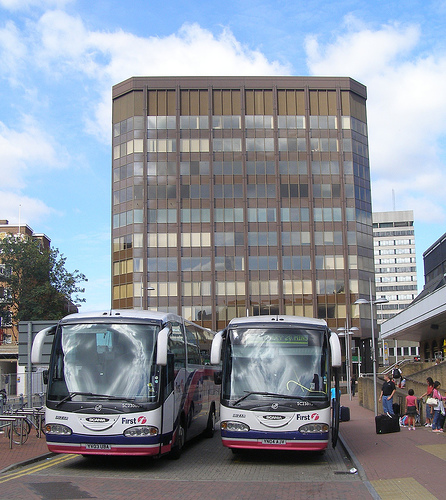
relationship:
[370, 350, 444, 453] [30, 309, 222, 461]
people in bus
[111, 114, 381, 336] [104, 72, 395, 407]
windows on building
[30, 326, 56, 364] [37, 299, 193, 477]
mirror on bus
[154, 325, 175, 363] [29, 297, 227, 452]
mirror on bus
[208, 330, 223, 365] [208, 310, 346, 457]
mirror on bus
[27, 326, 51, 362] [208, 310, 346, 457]
mirror on bus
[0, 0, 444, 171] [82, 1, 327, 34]
cloud on blue sky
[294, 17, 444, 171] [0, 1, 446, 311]
cloud on sky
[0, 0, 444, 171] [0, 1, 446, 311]
cloud on sky